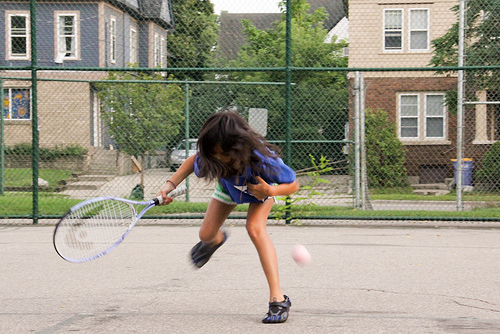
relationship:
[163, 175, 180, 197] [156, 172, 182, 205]
tie on wrist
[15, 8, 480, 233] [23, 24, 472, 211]
chain on fence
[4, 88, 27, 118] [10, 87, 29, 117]
decorative curtain on window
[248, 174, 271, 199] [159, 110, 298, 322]
hand on person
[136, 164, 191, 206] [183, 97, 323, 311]
hand on person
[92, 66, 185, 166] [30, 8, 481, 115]
tree behind fence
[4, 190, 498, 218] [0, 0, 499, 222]
grass behind fence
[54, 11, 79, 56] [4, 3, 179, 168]
window on house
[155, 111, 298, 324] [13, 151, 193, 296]
girl holding racket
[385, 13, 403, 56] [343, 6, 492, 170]
windows on house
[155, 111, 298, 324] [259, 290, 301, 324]
girl has foot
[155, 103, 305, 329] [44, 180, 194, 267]
girl with racket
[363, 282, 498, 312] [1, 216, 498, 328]
crack in pavement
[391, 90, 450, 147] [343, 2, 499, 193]
window on house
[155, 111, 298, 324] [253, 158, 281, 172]
girl wearing shirt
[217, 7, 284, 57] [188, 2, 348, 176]
roof on house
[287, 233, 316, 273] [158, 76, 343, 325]
ball heading toward girl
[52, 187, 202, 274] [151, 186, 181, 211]
racket in hand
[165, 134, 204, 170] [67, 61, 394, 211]
car behind fence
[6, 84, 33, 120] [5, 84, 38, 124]
fabric in window